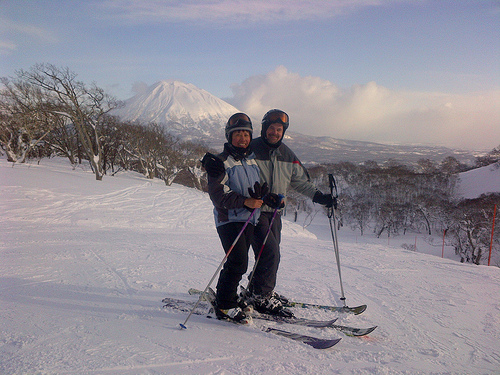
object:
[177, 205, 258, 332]
poles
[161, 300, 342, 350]
skis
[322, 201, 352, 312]
poles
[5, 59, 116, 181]
trees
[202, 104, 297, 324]
couple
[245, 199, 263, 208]
hand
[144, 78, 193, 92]
peak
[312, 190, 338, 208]
hand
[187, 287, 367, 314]
ski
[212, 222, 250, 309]
pants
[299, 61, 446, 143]
cloud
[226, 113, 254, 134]
helmet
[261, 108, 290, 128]
helmet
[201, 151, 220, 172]
arm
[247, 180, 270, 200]
glove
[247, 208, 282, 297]
pants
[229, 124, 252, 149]
head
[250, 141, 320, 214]
gray jacket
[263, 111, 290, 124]
goggles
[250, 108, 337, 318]
man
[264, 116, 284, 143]
head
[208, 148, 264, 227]
jacket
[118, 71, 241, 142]
mountain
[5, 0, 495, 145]
sky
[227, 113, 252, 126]
goggles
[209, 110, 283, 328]
woman